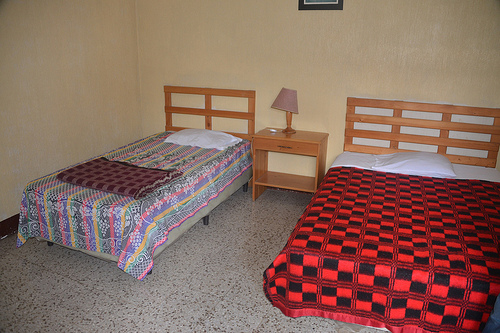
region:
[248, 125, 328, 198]
night stand to the right of a bed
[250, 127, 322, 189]
night stand to the left of a bed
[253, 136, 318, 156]
drawer on nightstand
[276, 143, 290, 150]
drawer pull on front of drawer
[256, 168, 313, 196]
shelf under nightstand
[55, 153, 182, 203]
checked blanket is folded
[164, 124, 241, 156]
white pillow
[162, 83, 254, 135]
light brown wooden headboard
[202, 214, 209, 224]
black feet under bed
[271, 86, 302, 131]
lamp on nightstand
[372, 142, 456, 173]
a white pillow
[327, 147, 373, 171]
part of a white sheet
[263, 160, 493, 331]
a red and black comforter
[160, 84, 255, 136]
a brown headboard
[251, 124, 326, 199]
a brown nightstand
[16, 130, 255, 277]
a colorful blanket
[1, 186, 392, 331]
white tile floor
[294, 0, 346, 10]
part of a black picture frame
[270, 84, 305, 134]
a small table lamp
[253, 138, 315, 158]
a brown wooden drawer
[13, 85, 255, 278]
bed is next to night stand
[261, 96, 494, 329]
bed is next to night stand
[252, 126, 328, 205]
night stand is wooden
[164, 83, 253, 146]
bed has wooden headboard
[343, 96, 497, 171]
bed has wooden headboard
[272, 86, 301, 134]
lamp on top of wooden table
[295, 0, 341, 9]
picture with black frame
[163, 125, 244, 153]
white pillow on bed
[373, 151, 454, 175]
white pillow on bed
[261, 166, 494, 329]
checkered blankekt covering bed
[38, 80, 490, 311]
two beds in a room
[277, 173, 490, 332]
red and black bed covering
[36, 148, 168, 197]
blanket on the bed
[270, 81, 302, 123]
lamp shade is crooked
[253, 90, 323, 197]
lamp on end table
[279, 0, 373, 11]
picture on the wall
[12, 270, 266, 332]
floor is tiled under beds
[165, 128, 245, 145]
white pillow on the bed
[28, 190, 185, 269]
multi colored bed cover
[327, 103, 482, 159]
headboard is made of wood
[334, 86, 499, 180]
wooden bed frame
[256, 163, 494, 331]
checkered bed spread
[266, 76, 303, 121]
the lampshade is crooked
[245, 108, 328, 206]
wooden night stand with one drawer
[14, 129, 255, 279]
floral patterned bed spread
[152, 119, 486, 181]
each bed has one small white pillow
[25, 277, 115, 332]
Grey floor with spots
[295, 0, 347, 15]
part of a picture frame can be seen on the wall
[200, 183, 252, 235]
the bed has black legs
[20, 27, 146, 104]
cream colored wall